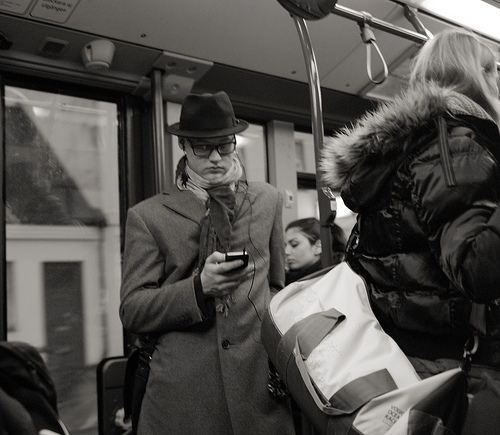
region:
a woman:
[185, 167, 342, 427]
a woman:
[94, 50, 259, 415]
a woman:
[134, 137, 224, 407]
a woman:
[151, 227, 218, 418]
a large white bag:
[258, 207, 477, 433]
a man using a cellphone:
[122, 96, 295, 426]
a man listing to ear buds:
[122, 91, 291, 427]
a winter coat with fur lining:
[315, 79, 493, 371]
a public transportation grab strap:
[348, 4, 390, 85]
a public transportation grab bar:
[338, 5, 497, 54]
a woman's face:
[283, 214, 330, 271]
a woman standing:
[310, 27, 491, 427]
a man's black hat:
[163, 89, 246, 144]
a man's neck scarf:
[179, 159, 241, 268]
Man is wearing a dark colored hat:
[151, 83, 252, 148]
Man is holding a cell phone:
[210, 232, 255, 289]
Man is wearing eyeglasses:
[176, 125, 241, 165]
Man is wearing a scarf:
[167, 150, 252, 250]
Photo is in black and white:
[5, 6, 491, 431]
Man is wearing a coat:
[110, 168, 295, 434]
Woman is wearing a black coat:
[323, 84, 498, 382]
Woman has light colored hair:
[367, 16, 498, 147]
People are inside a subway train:
[10, 8, 498, 414]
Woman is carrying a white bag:
[257, 218, 479, 433]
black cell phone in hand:
[196, 248, 263, 294]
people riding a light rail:
[3, 3, 495, 417]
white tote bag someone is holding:
[266, 260, 461, 425]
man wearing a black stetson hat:
[165, 80, 249, 146]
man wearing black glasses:
[188, 137, 236, 154]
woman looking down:
[279, 204, 330, 266]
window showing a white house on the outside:
[4, 54, 127, 379]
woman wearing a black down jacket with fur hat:
[323, 80, 495, 344]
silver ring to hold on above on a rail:
[353, 0, 398, 90]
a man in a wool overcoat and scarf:
[123, 82, 307, 434]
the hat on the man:
[168, 92, 249, 137]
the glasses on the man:
[180, 133, 239, 156]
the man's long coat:
[121, 177, 289, 433]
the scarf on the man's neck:
[182, 160, 247, 270]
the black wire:
[233, 153, 270, 351]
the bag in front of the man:
[270, 234, 454, 434]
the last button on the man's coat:
[222, 335, 234, 350]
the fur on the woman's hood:
[301, 89, 489, 185]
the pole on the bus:
[294, 11, 338, 276]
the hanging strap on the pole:
[355, 17, 385, 86]